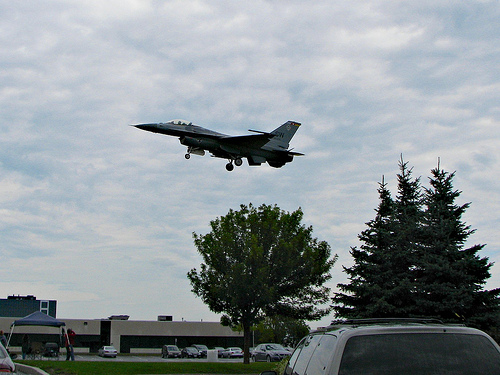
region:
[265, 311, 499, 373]
gray dirty van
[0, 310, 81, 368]
small blue tent pavilion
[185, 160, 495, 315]
green trees under plane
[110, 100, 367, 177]
gray and white military jet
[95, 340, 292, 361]
cars in parking lot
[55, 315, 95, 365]
man in red shirt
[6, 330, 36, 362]
woman in gray shirt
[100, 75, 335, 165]
military jet flying low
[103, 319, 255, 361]
brown building with black windows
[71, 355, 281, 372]
green grass next to parking lot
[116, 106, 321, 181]
airplane in the air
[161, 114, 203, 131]
cockpit of an airplane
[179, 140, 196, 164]
front wheel of an airplane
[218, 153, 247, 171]
rear wheels on an airplane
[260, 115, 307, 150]
tail wing on an airplane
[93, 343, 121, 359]
car parked in a lot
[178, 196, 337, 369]
tree in the grass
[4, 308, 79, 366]
blue canopy tent on the grass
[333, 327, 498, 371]
rear window on a vehicle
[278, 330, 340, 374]
side windows on a vehicle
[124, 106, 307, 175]
gray military fighter jet flying over parking lot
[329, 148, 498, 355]
small cluster of three evergreen trees next to parking lot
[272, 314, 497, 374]
dark gray car parked in parking lot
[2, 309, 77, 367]
blue square tent next to parking lot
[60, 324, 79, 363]
person with red shirt walking near parking lot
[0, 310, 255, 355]
flat long building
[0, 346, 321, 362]
long narrow gray concrete parking lot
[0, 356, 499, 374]
strip of green grass between parking lots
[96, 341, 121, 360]
car parked next to building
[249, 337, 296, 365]
car parked next to tree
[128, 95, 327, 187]
a fighter jet flying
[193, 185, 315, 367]
a green tree planted in the ground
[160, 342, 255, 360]
cars parked in a parking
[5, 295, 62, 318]
a grey building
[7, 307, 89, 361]
a small blue tent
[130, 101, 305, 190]
a fighter jet has it's landing wheels out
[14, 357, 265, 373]
a green lawn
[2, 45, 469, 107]
a cloudy day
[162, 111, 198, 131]
a pilot inside a fighter jet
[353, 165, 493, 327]
three pine trees planted in the ground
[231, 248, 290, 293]
The tree is green.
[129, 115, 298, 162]
Plane in the sky.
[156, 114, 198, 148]
Pilot in the cockpit.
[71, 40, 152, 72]
Clouds in the sky.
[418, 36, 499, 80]
Blue sky behind the clouds.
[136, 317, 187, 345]
Part of the building is beige.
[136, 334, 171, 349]
The windows are black.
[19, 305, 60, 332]
The tent is blue.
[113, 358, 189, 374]
The grass is green.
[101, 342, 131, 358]
Lone white car in the background.